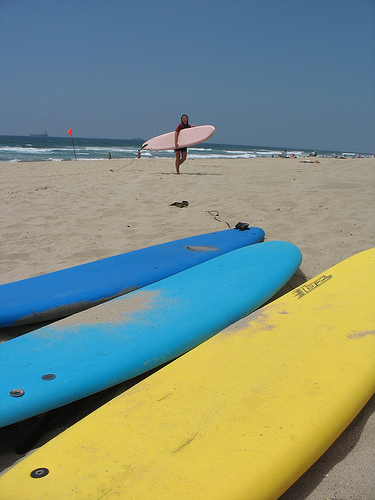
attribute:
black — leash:
[107, 143, 151, 174]